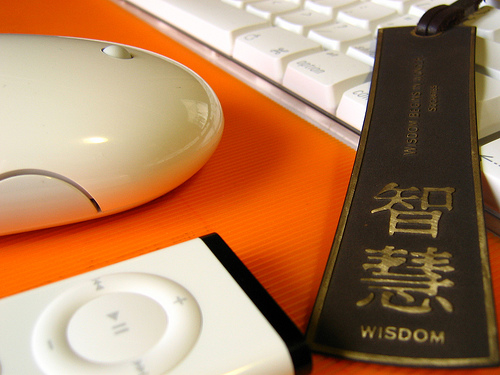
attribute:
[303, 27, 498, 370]
bookmark — black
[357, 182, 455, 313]
character — wisdom, chinese, written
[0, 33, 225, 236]
mouse — old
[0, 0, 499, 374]
pad — orange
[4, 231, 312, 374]
remote — white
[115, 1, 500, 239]
keyboard — white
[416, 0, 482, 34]
clip — small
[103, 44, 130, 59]
clicker — small